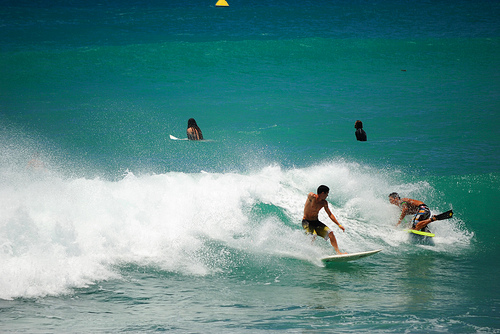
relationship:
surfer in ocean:
[283, 189, 360, 245] [59, 58, 139, 122]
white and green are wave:
[76, 129, 156, 177] [43, 193, 179, 279]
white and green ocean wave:
[76, 129, 156, 177] [43, 193, 179, 279]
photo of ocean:
[119, 91, 332, 173] [59, 58, 139, 122]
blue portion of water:
[223, 12, 308, 47] [192, 61, 329, 110]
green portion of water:
[44, 81, 124, 126] [192, 61, 329, 110]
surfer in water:
[283, 189, 360, 245] [192, 61, 329, 110]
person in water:
[154, 97, 223, 156] [192, 61, 329, 110]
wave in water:
[43, 193, 184, 301] [192, 61, 329, 110]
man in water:
[296, 178, 345, 258] [192, 61, 329, 110]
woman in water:
[154, 97, 223, 156] [192, 61, 329, 110]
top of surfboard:
[335, 237, 401, 266] [310, 254, 375, 266]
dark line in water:
[300, 11, 353, 23] [192, 61, 329, 110]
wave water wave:
[43, 193, 179, 279] [43, 193, 184, 301]